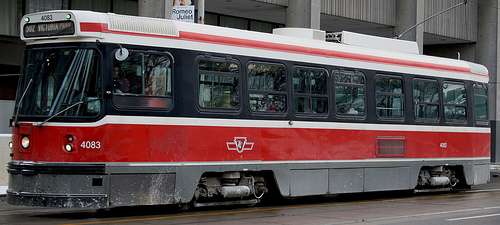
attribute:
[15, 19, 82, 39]
sign — displaying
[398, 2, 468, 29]
pole — metal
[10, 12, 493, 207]
trolly — electrical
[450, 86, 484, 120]
window — glass, clear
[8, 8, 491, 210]
bus — red, white, black, grey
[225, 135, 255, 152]
design — white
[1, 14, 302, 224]
tram — red, white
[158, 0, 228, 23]
sign — white, black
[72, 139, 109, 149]
tram number — white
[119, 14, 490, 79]
roof — white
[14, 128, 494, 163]
background — red